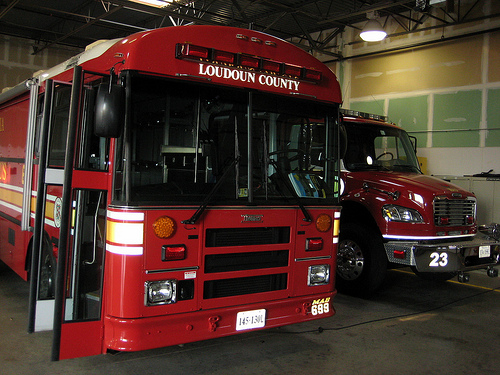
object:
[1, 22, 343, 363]
truck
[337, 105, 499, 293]
truck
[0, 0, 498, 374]
shed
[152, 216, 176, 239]
light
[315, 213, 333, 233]
light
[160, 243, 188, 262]
light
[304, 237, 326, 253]
light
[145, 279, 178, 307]
light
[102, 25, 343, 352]
front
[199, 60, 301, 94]
letters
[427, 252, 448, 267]
number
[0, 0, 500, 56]
rod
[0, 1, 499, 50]
ceiling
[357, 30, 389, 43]
light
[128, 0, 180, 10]
light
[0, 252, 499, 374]
floor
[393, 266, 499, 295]
line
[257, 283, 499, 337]
line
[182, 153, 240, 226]
windshield wiper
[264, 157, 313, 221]
windshield wiper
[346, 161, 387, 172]
windshield wiper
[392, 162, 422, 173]
windshield wiper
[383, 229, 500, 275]
bumper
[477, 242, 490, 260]
license plate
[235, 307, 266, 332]
license plate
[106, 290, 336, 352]
bumper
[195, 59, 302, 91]
louden county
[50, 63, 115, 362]
door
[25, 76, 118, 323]
door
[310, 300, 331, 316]
number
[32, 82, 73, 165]
window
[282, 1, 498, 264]
wall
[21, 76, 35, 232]
guard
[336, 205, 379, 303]
wheel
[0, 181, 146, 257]
stripes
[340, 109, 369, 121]
light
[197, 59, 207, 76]
letter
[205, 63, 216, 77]
letter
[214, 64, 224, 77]
letter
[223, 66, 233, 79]
letter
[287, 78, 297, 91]
letter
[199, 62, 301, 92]
letter